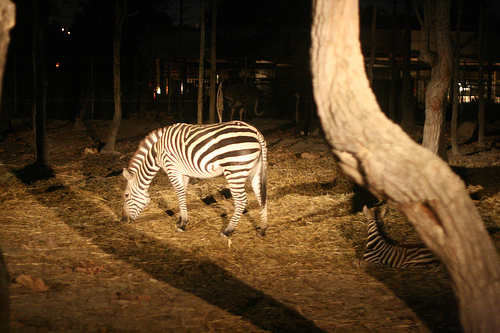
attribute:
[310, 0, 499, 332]
tree — tall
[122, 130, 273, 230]
zebra — small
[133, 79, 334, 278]
zebra — standing, grazing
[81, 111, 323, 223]
zebra — striped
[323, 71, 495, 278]
tree trunk — brown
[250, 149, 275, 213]
tail — black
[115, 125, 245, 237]
zebra — eating hay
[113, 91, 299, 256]
zebra — standing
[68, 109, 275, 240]
zebra — striped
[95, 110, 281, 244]
zebra — striped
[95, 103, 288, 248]
zebra — grazing, standing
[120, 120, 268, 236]
zebra — striped, standing, grazing, eating, black and white